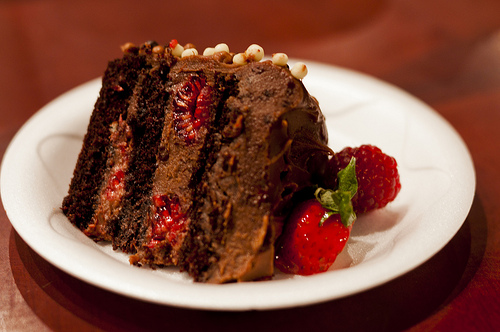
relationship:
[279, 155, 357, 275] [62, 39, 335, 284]
strawberry beside cake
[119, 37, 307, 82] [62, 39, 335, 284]
nuts on top of cake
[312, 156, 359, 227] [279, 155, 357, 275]
leaf on top of strawberry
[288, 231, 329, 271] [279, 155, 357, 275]
seeds inside of strawberry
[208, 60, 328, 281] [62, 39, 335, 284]
icing on top of cake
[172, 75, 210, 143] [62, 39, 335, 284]
strawberry inside of cake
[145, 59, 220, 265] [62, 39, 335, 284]
chocolate inside of cake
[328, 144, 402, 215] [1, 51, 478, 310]
raspberry on top of dish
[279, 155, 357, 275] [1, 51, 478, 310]
strawberry on top of dish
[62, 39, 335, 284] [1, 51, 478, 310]
cake on top of dish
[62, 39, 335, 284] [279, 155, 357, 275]
cake containing strawberry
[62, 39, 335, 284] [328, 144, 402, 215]
cake containing raspberry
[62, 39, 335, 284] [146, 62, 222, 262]
cake containing layers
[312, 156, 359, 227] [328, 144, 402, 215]
leaf on top of raspberry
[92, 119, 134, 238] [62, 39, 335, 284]
frosting inside of cake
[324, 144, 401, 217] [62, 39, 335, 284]
raspberry on top of cake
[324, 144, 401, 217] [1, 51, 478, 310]
raspberry on top of dish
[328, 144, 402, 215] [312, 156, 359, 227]
raspberry behind leaf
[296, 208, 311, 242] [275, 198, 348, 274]
reflection on top of skin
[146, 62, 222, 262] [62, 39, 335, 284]
layers inside of cake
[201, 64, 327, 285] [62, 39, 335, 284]
frosting on top of cake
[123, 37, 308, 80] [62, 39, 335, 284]
decoration on top of cake